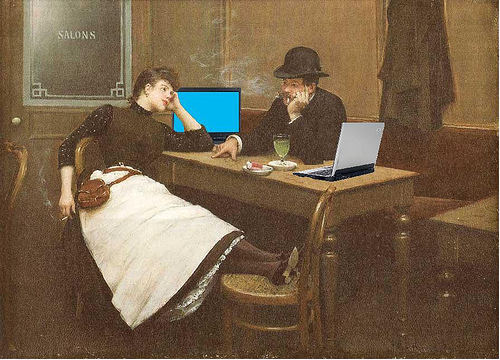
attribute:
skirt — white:
[79, 171, 242, 330]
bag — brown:
[75, 176, 112, 212]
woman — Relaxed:
[58, 64, 303, 327]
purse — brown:
[78, 161, 128, 211]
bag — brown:
[73, 176, 120, 214]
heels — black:
[270, 231, 312, 288]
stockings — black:
[233, 242, 275, 277]